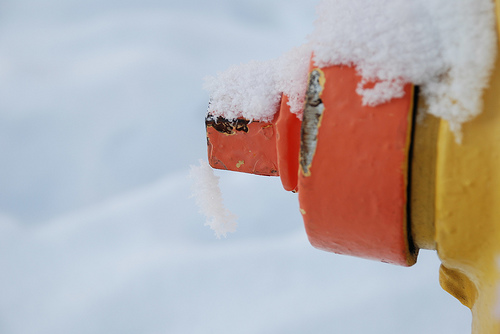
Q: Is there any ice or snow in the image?
A: Yes, there is snow.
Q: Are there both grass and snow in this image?
A: No, there is snow but no grass.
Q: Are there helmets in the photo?
A: No, there are no helmets.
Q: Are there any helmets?
A: No, there are no helmets.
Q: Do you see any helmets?
A: No, there are no helmets.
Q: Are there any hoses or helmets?
A: No, there are no helmets or hoses.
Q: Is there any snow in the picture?
A: Yes, there is snow.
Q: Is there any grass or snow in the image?
A: Yes, there is snow.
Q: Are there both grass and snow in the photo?
A: No, there is snow but no grass.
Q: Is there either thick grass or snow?
A: Yes, there is thick snow.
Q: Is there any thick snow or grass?
A: Yes, there is thick snow.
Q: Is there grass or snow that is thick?
A: Yes, the snow is thick.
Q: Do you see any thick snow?
A: Yes, there is thick snow.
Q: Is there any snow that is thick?
A: Yes, there is snow that is thick.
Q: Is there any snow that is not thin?
A: Yes, there is thick snow.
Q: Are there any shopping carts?
A: No, there are no shopping carts.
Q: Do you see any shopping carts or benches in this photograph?
A: No, there are no shopping carts or benches.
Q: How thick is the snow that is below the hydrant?
A: The snow is thick.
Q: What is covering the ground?
A: The snow is covering the ground.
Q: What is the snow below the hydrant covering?
A: The snow is covering the ground.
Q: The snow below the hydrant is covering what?
A: The snow is covering the ground.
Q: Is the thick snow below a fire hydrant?
A: Yes, the snow is below a fire hydrant.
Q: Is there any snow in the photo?
A: Yes, there is snow.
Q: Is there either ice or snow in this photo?
A: Yes, there is snow.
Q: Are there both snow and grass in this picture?
A: No, there is snow but no grass.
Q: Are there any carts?
A: No, there are no carts.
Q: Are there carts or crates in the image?
A: No, there are no carts or crates.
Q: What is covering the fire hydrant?
A: The snow is covering the fire hydrant.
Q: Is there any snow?
A: Yes, there is snow.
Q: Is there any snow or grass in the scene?
A: Yes, there is snow.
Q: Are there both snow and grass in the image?
A: No, there is snow but no grass.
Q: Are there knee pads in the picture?
A: No, there are no knee pads.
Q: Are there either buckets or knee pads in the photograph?
A: No, there are no knee pads or buckets.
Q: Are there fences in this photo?
A: No, there are no fences.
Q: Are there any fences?
A: No, there are no fences.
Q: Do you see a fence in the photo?
A: No, there are no fences.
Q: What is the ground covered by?
A: The ground is covered by the snow.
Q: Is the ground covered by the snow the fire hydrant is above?
A: Yes, the ground is covered by the snow.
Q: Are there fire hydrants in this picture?
A: Yes, there is a fire hydrant.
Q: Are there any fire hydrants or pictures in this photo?
A: Yes, there is a fire hydrant.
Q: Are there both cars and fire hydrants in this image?
A: No, there is a fire hydrant but no cars.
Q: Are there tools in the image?
A: No, there are no tools.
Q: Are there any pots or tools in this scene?
A: No, there are no tools or pots.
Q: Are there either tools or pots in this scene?
A: No, there are no tools or pots.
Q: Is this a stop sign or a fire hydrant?
A: This is a fire hydrant.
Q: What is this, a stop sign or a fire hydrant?
A: This is a fire hydrant.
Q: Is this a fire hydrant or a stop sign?
A: This is a fire hydrant.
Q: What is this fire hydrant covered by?
A: The fire hydrant is covered by the snow.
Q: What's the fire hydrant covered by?
A: The fire hydrant is covered by the snow.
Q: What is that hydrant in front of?
A: The hydrant is in front of the snow.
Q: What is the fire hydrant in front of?
A: The hydrant is in front of the snow.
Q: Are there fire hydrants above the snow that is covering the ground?
A: Yes, there is a fire hydrant above the snow.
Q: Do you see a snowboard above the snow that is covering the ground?
A: No, there is a fire hydrant above the snow.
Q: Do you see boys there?
A: No, there are no boys.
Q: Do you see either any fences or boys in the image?
A: No, there are no boys or fences.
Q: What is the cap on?
A: The cap is on the hydrant.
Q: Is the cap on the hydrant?
A: Yes, the cap is on the hydrant.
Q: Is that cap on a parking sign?
A: No, the cap is on the hydrant.